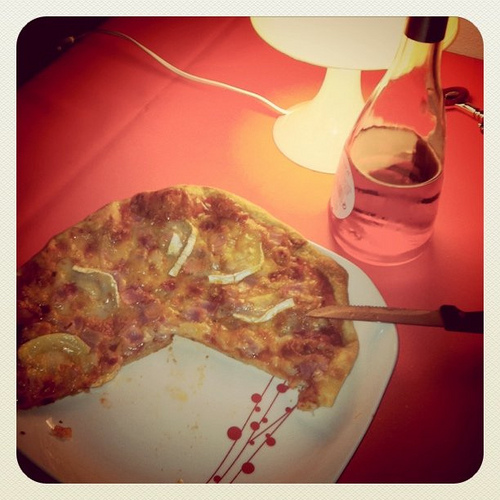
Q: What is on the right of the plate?
A: A bottle with clear liquid.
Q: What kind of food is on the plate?
A: Pizza.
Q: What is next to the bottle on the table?
A: A lamp.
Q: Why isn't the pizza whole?
A: Some slices are missing.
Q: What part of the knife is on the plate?
A: The silver part of the knife.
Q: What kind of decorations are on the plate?
A: Red circles and lines.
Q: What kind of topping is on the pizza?
A: Cheese and mushrooms.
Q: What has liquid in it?
A: The glass.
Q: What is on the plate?
A: Pizza.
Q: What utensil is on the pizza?
A: Steak knife.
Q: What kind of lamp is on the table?
A: White table lamp.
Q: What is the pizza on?
A: Plate.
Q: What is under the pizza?
A: Plate.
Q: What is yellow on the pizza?
A: Cheese.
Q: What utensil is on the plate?
A: Knife.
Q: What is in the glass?
A: Liquid.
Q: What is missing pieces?
A: Pizza.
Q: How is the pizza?
A: Partially eaten.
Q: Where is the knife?
A: On plate.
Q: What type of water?
A: Carbonated.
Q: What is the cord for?
A: Lamp.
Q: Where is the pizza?
A: On table.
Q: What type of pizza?
A: Cheesy.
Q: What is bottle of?
A: Wine.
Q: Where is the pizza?
A: On the plate.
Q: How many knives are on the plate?
A: One.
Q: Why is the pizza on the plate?
A: To be eaten.